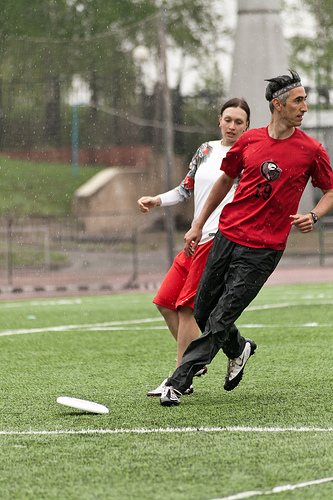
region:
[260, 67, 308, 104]
wet hair near a bandana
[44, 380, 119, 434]
frisbee landing on the ground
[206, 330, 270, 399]
black and white sports shoe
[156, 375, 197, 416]
black and white sports shoe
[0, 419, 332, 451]
line painted in the grass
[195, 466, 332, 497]
line painted in the grass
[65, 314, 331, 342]
line painted in the grass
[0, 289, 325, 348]
line painted in the grass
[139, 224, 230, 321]
pair of red shorts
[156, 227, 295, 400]
pair of black pants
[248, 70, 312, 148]
a man wearing a head band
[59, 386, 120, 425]
a white frisbee on the ground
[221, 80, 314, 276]
a man wearing a red shirt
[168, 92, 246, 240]
a woman wearing a white shirt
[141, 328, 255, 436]
a man wearing white and black shoes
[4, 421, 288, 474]
white chalk lines on a field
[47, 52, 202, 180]
rain drops falling from the sky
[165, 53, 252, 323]
a woman wearing red shorts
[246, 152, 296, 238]
the number 19 on a man's shirt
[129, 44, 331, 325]
two people running in a field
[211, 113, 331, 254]
a red man's shirt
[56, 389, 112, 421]
this is a frisbee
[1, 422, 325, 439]
this is a white line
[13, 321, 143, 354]
a white painted line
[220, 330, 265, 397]
the right men's cleat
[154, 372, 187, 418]
the left men's cleat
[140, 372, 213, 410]
the left woman's cleat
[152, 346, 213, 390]
the right woman's cleat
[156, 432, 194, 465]
the color grass green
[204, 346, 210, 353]
this is the color black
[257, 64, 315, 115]
Man has dark hair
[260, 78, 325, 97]
Man wearing a headband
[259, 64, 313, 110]
Hair is graying at temple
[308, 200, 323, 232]
Man wearing a wrist watch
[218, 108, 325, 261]
Man wearing red T shirt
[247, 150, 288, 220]
Shirt has team logo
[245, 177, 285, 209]
Red shirt has number 19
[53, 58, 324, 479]
Man and woman playing with frisbee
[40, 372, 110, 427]
White frisbee laying on ground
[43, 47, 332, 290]
Man and woman playing in rain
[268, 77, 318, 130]
man looking to his right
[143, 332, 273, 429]
shoes of the man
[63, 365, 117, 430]
Frisbee on the ground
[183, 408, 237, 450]
white line on the ground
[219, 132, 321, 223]
red shirt on the man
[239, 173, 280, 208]
the number 19 on man's shirt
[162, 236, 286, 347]
black pants on man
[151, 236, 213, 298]
red shorts on girl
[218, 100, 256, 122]
woman with brown hair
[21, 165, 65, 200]
blurry grass in the background